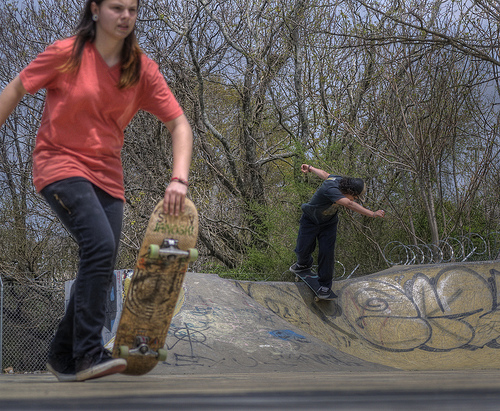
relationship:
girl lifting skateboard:
[1, 0, 194, 381] [111, 196, 200, 377]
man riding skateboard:
[289, 162, 384, 300] [289, 262, 339, 305]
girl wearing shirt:
[1, 0, 194, 381] [21, 35, 186, 201]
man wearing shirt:
[289, 162, 384, 300] [301, 174, 346, 224]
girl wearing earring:
[1, 0, 194, 381] [91, 13, 98, 21]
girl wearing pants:
[1, 0, 194, 381] [38, 174, 127, 368]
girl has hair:
[1, 0, 194, 381] [54, 0, 143, 90]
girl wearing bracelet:
[1, 0, 194, 381] [167, 174, 188, 190]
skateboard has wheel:
[111, 196, 200, 377] [147, 242, 162, 263]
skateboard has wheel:
[111, 196, 200, 377] [187, 246, 198, 262]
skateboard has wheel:
[111, 196, 200, 377] [117, 346, 129, 359]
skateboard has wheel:
[111, 196, 200, 377] [155, 346, 168, 362]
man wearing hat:
[289, 162, 384, 300] [346, 174, 369, 203]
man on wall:
[289, 162, 384, 300] [64, 259, 498, 377]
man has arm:
[289, 162, 384, 300] [299, 162, 331, 178]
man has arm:
[289, 162, 384, 300] [338, 195, 385, 222]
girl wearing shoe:
[1, 0, 194, 381] [41, 355, 79, 382]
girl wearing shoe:
[1, 0, 194, 381] [72, 350, 129, 382]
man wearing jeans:
[289, 162, 384, 300] [295, 216, 338, 286]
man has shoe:
[289, 162, 384, 300] [289, 257, 314, 273]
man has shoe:
[289, 162, 384, 300] [316, 284, 332, 300]